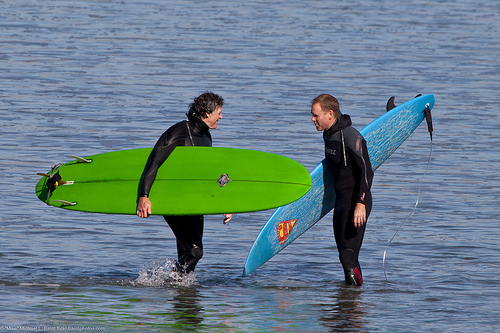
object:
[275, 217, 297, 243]
design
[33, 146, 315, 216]
green board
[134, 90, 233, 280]
man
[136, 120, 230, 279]
wet suit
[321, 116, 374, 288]
man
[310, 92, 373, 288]
man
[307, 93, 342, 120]
hair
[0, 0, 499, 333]
water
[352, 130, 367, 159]
markings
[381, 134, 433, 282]
line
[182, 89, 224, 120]
hair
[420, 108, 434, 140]
fins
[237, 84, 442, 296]
surfboard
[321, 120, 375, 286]
wetsuit